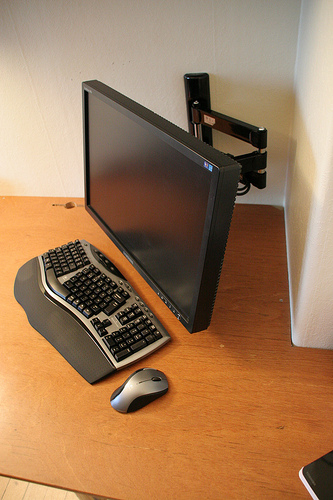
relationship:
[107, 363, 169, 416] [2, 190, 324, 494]
mouse on desk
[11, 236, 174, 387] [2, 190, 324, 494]
keyboard on desk